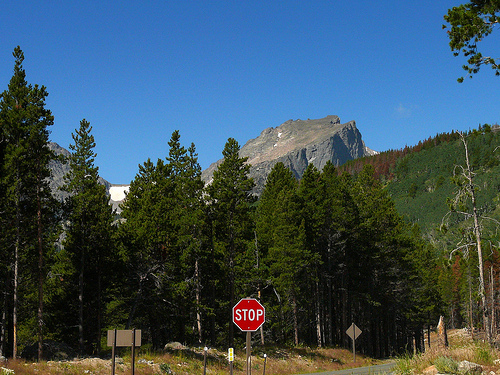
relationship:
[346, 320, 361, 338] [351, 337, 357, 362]
rhombus signboard in pole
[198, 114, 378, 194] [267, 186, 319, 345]
mountain behind pine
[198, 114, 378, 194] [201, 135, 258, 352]
mountain behind tree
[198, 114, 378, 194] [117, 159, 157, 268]
mountain behind pine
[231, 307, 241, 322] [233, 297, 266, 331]
letter on sign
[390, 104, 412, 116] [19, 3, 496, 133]
cloud in blue sky